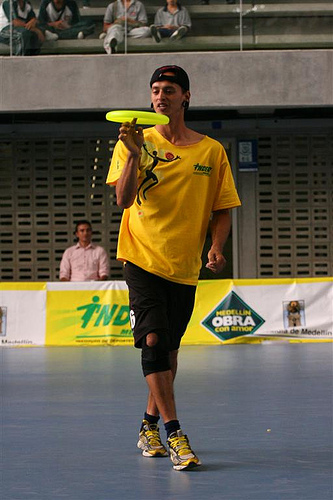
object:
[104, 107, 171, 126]
frisbee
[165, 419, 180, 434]
socks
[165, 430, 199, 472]
sneakers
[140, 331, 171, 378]
brace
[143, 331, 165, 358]
knee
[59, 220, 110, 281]
man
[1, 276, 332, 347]
banner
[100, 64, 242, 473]
man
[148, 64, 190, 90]
hat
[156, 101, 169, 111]
mouth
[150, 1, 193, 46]
people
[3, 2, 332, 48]
bleachers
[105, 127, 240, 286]
shirt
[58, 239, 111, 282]
shirt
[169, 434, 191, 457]
laces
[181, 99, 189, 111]
earring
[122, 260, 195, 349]
shorts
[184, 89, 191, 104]
ear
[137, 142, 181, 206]
design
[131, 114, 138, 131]
finger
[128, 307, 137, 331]
number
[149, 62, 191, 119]
head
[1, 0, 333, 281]
building